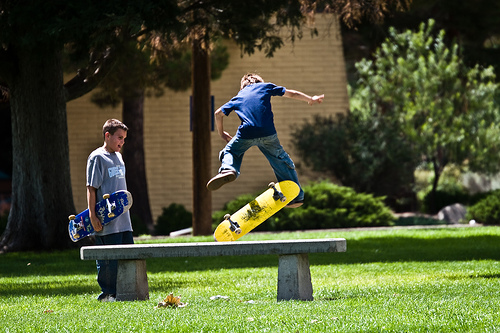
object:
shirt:
[221, 82, 287, 139]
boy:
[205, 72, 325, 208]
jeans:
[217, 136, 306, 201]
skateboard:
[212, 180, 301, 245]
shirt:
[84, 147, 135, 237]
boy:
[88, 118, 136, 302]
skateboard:
[67, 189, 133, 242]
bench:
[79, 238, 347, 304]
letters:
[108, 165, 126, 179]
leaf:
[157, 292, 186, 309]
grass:
[1, 220, 500, 331]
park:
[0, 200, 500, 333]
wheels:
[268, 181, 288, 202]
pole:
[189, 2, 212, 234]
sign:
[188, 95, 215, 132]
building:
[61, 4, 354, 219]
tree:
[0, 0, 178, 242]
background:
[0, 0, 499, 160]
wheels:
[103, 194, 116, 218]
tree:
[349, 17, 500, 210]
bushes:
[211, 180, 386, 229]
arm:
[86, 162, 105, 232]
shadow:
[2, 249, 96, 278]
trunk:
[1, 0, 79, 251]